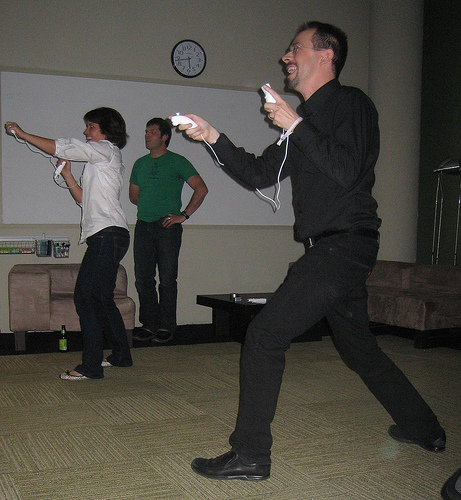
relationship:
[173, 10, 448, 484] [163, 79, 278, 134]
man playing wii game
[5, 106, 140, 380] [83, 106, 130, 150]
female with dark hair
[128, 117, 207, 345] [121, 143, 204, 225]
guy in shirt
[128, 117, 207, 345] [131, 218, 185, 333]
guy wearing pants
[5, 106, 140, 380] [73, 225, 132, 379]
female wearing jeans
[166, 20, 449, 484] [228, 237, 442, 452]
man wearing pants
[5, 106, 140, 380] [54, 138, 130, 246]
female wearing blouse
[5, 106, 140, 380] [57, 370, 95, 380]
female wearing flipflop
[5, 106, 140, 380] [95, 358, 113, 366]
female wearing flipflop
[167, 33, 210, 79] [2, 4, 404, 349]
clock on wall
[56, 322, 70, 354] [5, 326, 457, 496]
bottle on floor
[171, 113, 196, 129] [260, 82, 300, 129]
game controller in hand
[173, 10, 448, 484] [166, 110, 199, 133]
man holding wii controller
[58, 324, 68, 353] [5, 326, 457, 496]
bottle sitting on floor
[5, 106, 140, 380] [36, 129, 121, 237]
female wearing blouse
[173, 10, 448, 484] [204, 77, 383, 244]
man wearing shirt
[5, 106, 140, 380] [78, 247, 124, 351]
female in jeans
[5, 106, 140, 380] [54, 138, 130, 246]
female in blouse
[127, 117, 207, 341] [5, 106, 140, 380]
guy watching female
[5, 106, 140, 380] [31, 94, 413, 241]
female play play games